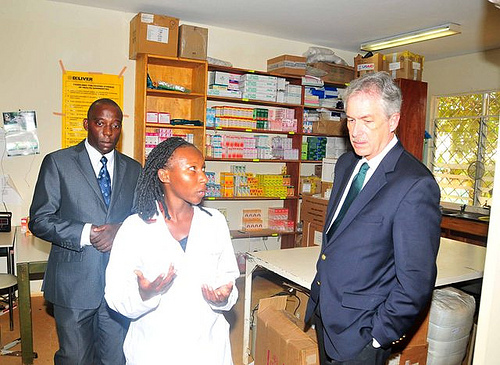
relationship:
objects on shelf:
[190, 74, 315, 194] [142, 115, 202, 132]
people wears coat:
[98, 134, 236, 365] [102, 202, 252, 362]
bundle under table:
[430, 278, 480, 363] [230, 224, 488, 364]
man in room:
[300, 71, 441, 362] [1, 1, 498, 363]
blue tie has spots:
[95, 154, 115, 207] [101, 178, 111, 192]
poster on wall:
[0, 110, 41, 157] [2, 73, 49, 191]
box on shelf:
[126, 10, 181, 63] [135, 49, 207, 139]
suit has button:
[300, 141, 440, 363] [319, 254, 326, 260]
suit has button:
[300, 141, 440, 363] [313, 280, 320, 285]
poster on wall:
[0, 105, 43, 157] [4, 2, 134, 227]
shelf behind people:
[146, 82, 201, 102] [98, 134, 236, 365]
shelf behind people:
[142, 115, 202, 132] [98, 134, 236, 365]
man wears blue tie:
[300, 131, 443, 363] [323, 160, 375, 247]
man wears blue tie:
[27, 98, 151, 363] [92, 154, 114, 207]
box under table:
[247, 291, 320, 363] [238, 236, 320, 359]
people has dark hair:
[98, 134, 236, 365] [131, 136, 192, 218]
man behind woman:
[27, 98, 151, 363] [110, 132, 235, 360]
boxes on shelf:
[147, 113, 169, 123] [141, 94, 207, 124]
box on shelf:
[129, 11, 181, 62] [142, 54, 207, 94]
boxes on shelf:
[358, 51, 423, 78] [401, 77, 425, 156]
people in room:
[127, 134, 237, 364] [1, 1, 498, 363]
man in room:
[27, 98, 151, 363] [1, 1, 498, 363]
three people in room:
[29, 70, 439, 364] [1, 1, 498, 363]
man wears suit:
[27, 98, 151, 363] [25, 140, 142, 362]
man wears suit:
[300, 71, 441, 362] [300, 141, 440, 363]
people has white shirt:
[98, 134, 236, 365] [98, 208, 245, 362]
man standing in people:
[300, 71, 441, 362] [98, 134, 236, 365]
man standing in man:
[300, 71, 441, 362] [27, 98, 151, 363]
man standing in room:
[300, 71, 441, 362] [1, 1, 498, 363]